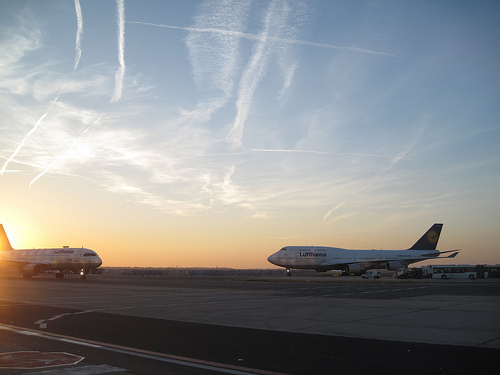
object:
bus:
[431, 263, 499, 279]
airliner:
[267, 221, 460, 276]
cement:
[1, 273, 499, 375]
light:
[9, 225, 51, 250]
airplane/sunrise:
[2, 222, 95, 250]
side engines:
[345, 263, 361, 274]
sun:
[1, 212, 28, 257]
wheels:
[362, 276, 365, 279]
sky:
[0, 0, 499, 268]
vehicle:
[361, 269, 383, 279]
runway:
[1, 277, 497, 374]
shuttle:
[431, 266, 498, 281]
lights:
[286, 269, 290, 273]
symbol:
[0, 349, 85, 370]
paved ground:
[0, 274, 500, 375]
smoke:
[1, 0, 124, 199]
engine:
[24, 264, 40, 275]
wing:
[2, 258, 51, 266]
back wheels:
[22, 272, 30, 280]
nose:
[267, 252, 281, 263]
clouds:
[48, 54, 283, 222]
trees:
[102, 261, 280, 283]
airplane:
[0, 222, 102, 279]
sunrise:
[3, 196, 37, 250]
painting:
[0, 346, 85, 371]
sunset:
[0, 198, 224, 285]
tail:
[0, 220, 13, 252]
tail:
[409, 220, 444, 251]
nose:
[87, 256, 102, 267]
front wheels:
[79, 275, 86, 280]